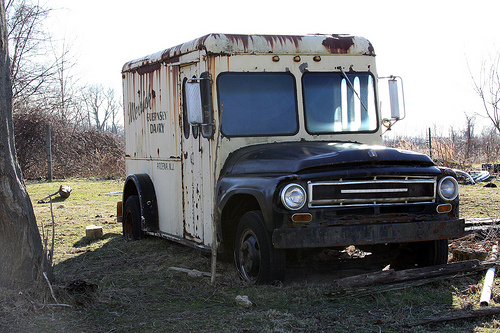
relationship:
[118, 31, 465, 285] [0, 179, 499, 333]
truck on top of grass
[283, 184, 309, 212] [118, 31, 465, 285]
light on truck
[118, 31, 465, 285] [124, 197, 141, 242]
truck has wheel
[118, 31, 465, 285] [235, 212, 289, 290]
truck has wheel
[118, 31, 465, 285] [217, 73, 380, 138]
truck has windshield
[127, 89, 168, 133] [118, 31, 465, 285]
writing on side of truck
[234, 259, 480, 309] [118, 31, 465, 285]
log in front of truck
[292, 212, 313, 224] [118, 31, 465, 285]
turnsignal on side of truck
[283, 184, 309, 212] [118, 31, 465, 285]
light on front of truck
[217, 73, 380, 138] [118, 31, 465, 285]
windshield on front of truck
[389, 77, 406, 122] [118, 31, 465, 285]
mirror on side of truck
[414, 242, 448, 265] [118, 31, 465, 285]
wheel on front of truck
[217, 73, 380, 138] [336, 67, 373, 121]
windshield has wiper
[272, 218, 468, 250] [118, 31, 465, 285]
bumper on front of truck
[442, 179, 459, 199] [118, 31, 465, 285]
light on truck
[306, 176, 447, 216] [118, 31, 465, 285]
grill on front of truck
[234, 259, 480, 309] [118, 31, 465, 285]
log near truck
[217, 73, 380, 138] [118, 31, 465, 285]
windshield of truck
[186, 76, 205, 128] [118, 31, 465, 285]
mirror on side of truck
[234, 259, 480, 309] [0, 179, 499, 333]
log on top of grass